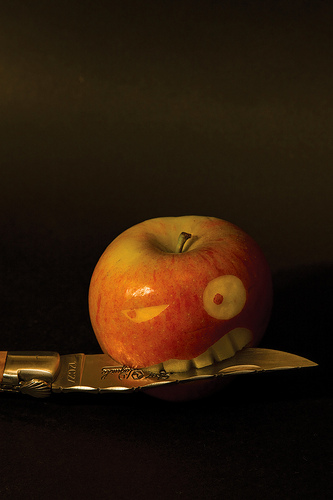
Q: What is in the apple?
A: Knife.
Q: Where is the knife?
A: In the apple.